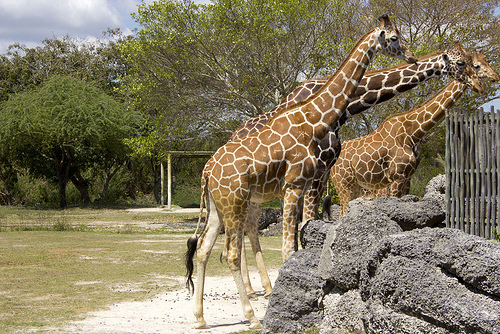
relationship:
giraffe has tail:
[181, 32, 407, 301] [183, 168, 195, 278]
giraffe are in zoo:
[182, 12, 411, 332] [4, 107, 497, 332]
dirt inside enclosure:
[29, 268, 279, 331] [3, 9, 499, 323]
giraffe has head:
[326, 50, 499, 218] [370, 11, 418, 69]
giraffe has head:
[223, 41, 498, 297] [443, 35, 483, 97]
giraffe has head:
[223, 41, 498, 297] [462, 43, 498, 88]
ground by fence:
[95, 271, 249, 332] [430, 102, 485, 211]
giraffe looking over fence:
[182, 12, 411, 332] [434, 114, 484, 233]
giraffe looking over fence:
[223, 41, 498, 297] [434, 114, 484, 233]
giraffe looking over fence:
[326, 50, 499, 218] [434, 114, 484, 233]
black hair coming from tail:
[183, 236, 200, 296] [180, 168, 208, 284]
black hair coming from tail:
[183, 236, 200, 296] [166, 161, 237, 310]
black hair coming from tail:
[183, 236, 200, 296] [185, 164, 207, 295]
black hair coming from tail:
[183, 236, 200, 296] [186, 160, 213, 285]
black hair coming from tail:
[183, 236, 200, 296] [184, 174, 206, 294]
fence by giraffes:
[445, 112, 495, 232] [216, 32, 478, 268]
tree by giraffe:
[17, 65, 126, 217] [182, 12, 411, 332]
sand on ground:
[101, 297, 190, 332] [46, 224, 219, 324]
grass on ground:
[10, 246, 95, 308] [46, 224, 219, 324]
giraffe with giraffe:
[182, 12, 411, 332] [326, 50, 499, 218]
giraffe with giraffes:
[326, 50, 499, 218] [324, 50, 491, 226]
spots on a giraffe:
[284, 122, 314, 143] [182, 12, 411, 332]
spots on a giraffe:
[271, 113, 292, 136] [182, 12, 411, 332]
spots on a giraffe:
[288, 110, 302, 133] [182, 12, 411, 332]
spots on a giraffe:
[299, 102, 322, 125] [182, 12, 411, 332]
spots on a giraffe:
[251, 137, 276, 166] [182, 12, 411, 332]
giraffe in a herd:
[182, 12, 411, 332] [179, 11, 493, 331]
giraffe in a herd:
[314, 23, 485, 123] [179, 11, 493, 331]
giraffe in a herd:
[326, 50, 485, 209] [179, 11, 493, 331]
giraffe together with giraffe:
[182, 12, 411, 332] [223, 41, 498, 297]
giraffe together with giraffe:
[223, 41, 498, 297] [350, 58, 485, 197]